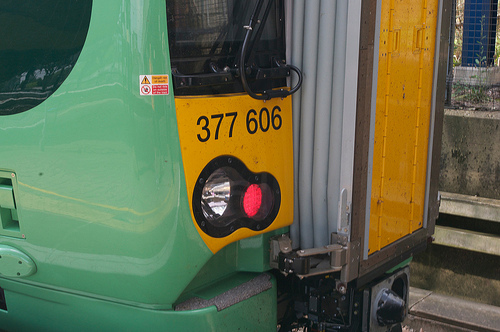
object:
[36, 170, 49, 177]
speck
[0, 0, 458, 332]
train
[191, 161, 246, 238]
headlights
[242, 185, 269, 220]
light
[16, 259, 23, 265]
bolts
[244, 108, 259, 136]
black number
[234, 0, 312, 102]
hose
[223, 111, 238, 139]
number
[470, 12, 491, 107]
plant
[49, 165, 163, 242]
reflection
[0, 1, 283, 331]
panel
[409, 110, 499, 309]
concrete wall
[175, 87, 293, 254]
yellow panel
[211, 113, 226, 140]
number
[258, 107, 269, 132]
number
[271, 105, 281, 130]
number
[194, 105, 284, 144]
377 606